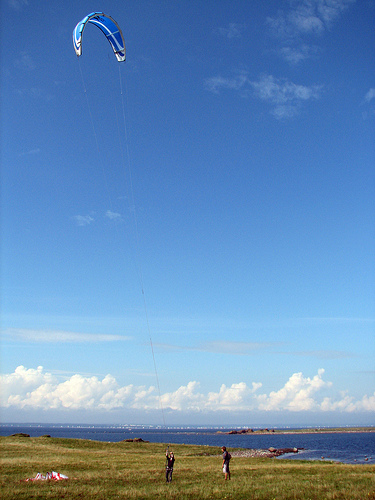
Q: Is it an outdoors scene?
A: Yes, it is outdoors.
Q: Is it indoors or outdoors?
A: It is outdoors.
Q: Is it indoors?
A: No, it is outdoors.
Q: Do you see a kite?
A: Yes, there is a kite.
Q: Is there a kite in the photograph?
A: Yes, there is a kite.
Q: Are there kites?
A: Yes, there is a kite.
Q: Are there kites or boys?
A: Yes, there is a kite.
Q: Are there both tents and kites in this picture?
A: No, there is a kite but no tents.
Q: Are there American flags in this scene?
A: No, there are no American flags.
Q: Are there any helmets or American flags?
A: No, there are no American flags or helmets.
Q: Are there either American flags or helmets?
A: No, there are no American flags or helmets.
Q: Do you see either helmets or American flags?
A: No, there are no American flags or helmets.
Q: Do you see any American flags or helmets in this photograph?
A: No, there are no American flags or helmets.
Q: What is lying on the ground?
A: The kite is lying on the ground.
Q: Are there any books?
A: No, there are no books.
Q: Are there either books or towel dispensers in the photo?
A: No, there are no books or towel dispensers.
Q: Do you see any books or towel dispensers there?
A: No, there are no books or towel dispensers.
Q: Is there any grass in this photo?
A: Yes, there is grass.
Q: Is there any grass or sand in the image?
A: Yes, there is grass.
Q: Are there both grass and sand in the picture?
A: No, there is grass but no sand.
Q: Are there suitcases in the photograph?
A: No, there are no suitcases.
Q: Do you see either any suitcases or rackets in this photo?
A: No, there are no suitcases or rackets.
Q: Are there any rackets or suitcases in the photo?
A: No, there are no suitcases or rackets.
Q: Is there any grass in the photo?
A: Yes, there is grass.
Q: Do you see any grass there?
A: Yes, there is grass.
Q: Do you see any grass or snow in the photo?
A: Yes, there is grass.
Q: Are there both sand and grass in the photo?
A: No, there is grass but no sand.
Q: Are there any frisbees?
A: No, there are no frisbees.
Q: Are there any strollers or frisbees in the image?
A: No, there are no frisbees or strollers.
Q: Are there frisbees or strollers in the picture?
A: No, there are no frisbees or strollers.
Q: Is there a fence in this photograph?
A: No, there are no fences.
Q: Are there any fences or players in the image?
A: No, there are no fences or players.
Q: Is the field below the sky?
A: Yes, the field is below the sky.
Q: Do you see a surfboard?
A: No, there are no surfboards.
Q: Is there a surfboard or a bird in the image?
A: No, there are no surfboards or birds.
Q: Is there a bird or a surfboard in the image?
A: No, there are no surfboards or birds.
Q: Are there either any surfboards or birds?
A: No, there are no surfboards or birds.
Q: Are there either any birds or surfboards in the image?
A: No, there are no surfboards or birds.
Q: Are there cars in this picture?
A: No, there are no cars.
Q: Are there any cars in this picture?
A: No, there are no cars.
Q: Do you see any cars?
A: No, there are no cars.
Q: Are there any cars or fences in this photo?
A: No, there are no cars or fences.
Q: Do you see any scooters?
A: No, there are no scooters.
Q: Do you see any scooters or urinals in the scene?
A: No, there are no scooters or urinals.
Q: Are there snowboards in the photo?
A: No, there are no snowboards.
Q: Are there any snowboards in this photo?
A: No, there are no snowboards.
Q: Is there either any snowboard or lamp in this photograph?
A: No, there are no snowboards or lamps.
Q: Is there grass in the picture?
A: Yes, there is grass.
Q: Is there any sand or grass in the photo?
A: Yes, there is grass.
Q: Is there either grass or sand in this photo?
A: Yes, there is grass.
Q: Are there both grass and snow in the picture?
A: No, there is grass but no snow.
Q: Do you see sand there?
A: No, there is no sand.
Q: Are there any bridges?
A: Yes, there is a bridge.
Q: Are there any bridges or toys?
A: Yes, there is a bridge.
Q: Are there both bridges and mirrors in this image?
A: No, there is a bridge but no mirrors.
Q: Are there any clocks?
A: No, there are no clocks.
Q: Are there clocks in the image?
A: No, there are no clocks.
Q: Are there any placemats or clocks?
A: No, there are no clocks or placemats.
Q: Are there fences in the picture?
A: No, there are no fences.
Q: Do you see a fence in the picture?
A: No, there are no fences.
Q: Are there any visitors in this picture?
A: No, there are no visitors.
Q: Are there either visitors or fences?
A: No, there are no visitors or fences.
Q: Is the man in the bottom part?
A: Yes, the man is in the bottom of the image.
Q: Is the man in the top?
A: No, the man is in the bottom of the image.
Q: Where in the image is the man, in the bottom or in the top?
A: The man is in the bottom of the image.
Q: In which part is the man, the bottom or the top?
A: The man is in the bottom of the image.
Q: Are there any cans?
A: No, there are no cans.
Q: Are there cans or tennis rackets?
A: No, there are no cans or tennis rackets.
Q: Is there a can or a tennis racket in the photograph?
A: No, there are no cans or rackets.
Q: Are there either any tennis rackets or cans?
A: No, there are no cans or tennis rackets.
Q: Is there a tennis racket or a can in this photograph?
A: No, there are no cans or rackets.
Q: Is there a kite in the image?
A: Yes, there is a kite.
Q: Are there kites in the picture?
A: Yes, there is a kite.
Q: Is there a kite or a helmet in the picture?
A: Yes, there is a kite.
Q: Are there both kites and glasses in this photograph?
A: No, there is a kite but no glasses.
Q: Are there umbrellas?
A: No, there are no umbrellas.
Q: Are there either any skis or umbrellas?
A: No, there are no umbrellas or skis.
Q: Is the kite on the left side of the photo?
A: Yes, the kite is on the left of the image.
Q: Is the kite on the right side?
A: No, the kite is on the left of the image.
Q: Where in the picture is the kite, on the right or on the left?
A: The kite is on the left of the image.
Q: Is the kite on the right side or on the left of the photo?
A: The kite is on the left of the image.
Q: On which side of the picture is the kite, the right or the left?
A: The kite is on the left of the image.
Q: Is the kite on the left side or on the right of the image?
A: The kite is on the left of the image.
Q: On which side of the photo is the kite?
A: The kite is on the left of the image.